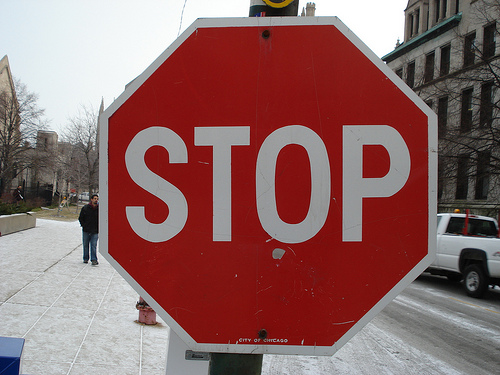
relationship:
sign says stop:
[79, 20, 441, 351] [119, 105, 394, 264]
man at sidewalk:
[75, 187, 98, 263] [19, 228, 116, 341]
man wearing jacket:
[75, 187, 98, 263] [78, 205, 104, 232]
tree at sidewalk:
[55, 124, 102, 214] [19, 228, 116, 341]